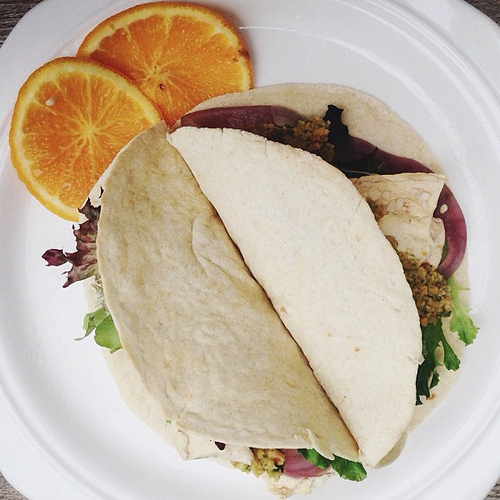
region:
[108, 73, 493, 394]
this is a dinner food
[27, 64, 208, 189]
these are sliced oranges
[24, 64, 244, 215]
the oranges are citrusy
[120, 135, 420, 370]
these are tacos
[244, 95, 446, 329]
the tacos are stuffed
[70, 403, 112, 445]
the plate is white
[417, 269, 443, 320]
the meat is brown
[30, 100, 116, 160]
an orange on the plate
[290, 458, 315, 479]
onions on the taco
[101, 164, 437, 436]
two tacos on the plate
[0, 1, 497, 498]
food on white plate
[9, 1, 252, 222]
two slices of orange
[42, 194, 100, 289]
uneaven edge of purple leaf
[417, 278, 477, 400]
green leaf over plate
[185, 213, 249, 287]
creases in flat bread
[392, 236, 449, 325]
food inside of flat bread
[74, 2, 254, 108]
skin around edge of orange slice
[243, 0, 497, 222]
light reflection on plate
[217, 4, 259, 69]
shadow of orange on plate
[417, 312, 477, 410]
the lettuce is green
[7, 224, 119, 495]
the plate is white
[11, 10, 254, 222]
the oranges are sliced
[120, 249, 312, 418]
the tortilla is white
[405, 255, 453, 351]
meat on the taco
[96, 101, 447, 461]
tacos on the plate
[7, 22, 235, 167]
two orange slices on the plate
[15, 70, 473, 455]
oranges beside the tacos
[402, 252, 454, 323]
the meat is brown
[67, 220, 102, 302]
the lettuce is purple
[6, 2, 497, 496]
this is a plate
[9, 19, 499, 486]
the plate is white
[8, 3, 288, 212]
oranges on the plate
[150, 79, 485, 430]
this is a tortilla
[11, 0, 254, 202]
There are two orange slices on the plate.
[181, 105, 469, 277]
The vegetable is purple.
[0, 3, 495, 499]
The plate is white in color.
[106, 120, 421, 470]
The bread is white.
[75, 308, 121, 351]
The lettuce is green.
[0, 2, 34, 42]
The table is made of wood.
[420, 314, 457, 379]
The lettuce is green.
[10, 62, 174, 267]
The orange is orange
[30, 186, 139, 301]
The cabbage is purple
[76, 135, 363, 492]
The tortilla is white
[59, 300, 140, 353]
The lettuce is green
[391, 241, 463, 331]
The rice is brown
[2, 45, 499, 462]
The plate is white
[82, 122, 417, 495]
The tortillas are touching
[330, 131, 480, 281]
The onion is purple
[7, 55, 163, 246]
The orange is round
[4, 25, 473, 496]
The food is on the plate